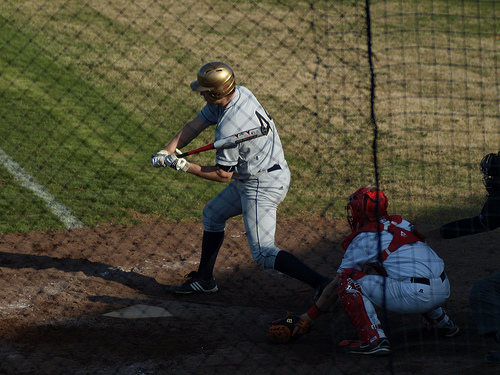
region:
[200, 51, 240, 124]
batter at plate has gold helmet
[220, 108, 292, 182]
batter has grey and black shirt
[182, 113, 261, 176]
batter is swinging red and black bat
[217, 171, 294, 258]
batter has black and grey pants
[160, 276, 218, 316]
batter has dark and striped shoes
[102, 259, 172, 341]
home plate is in shadow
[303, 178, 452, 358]
catcher has red helmet and guard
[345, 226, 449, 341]
catcher has white outfit with black belt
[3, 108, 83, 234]
white line on infield grass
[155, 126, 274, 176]
batter is swinging aluminum bat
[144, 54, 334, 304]
man with gold helmet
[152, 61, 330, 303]
man getting ready to swing bat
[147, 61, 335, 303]
man with number 44 on back of his shirt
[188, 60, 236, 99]
mans gold helmet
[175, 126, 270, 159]
red and silver bat the man is fixing to swing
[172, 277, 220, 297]
black and white tennis shoe of the batter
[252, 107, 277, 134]
Number 44 on the back of batters shirt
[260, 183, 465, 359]
man crouching behind batter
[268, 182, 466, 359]
man with red and white uniform on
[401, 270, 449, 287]
belt on the crouching man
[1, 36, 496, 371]
People playing a game of baseball.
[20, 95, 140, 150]
The grass is green.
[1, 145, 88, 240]
A line painted on the baseball field.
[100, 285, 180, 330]
The baseball diamond is on the dirt.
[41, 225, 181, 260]
Dirt is on the ground.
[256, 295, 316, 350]
The catcher is wearing a mitt.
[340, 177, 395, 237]
The catcher is wearing a mask.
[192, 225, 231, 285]
A knee sock on the batter.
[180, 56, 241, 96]
The baseball helmet is gold colored.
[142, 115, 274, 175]
The man is holding a bat.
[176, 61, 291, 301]
Player hitting a ball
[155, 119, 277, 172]
player holding a bat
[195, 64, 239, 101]
mans baseball helmet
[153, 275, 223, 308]
a black and white shoe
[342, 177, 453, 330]
catcher in white and red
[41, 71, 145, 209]
green grass on ball field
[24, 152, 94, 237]
white line on ball field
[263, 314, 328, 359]
catchers mitt in left hand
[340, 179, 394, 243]
red ball hat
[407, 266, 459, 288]
black belt around waist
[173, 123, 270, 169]
a red, black and silver baseball bat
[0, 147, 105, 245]
white line on the grass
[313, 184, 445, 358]
a catcher wearing red pads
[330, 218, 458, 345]
a catcher wearing a white uniform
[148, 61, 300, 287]
a batter wearing a gold helmet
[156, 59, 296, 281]
a batter wearing a grey uniform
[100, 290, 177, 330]
white home plate of the baseball field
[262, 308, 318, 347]
catcher's mitt being held to the ground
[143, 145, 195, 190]
the batter's white gloves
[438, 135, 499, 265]
an umpire with a black jacket and mask